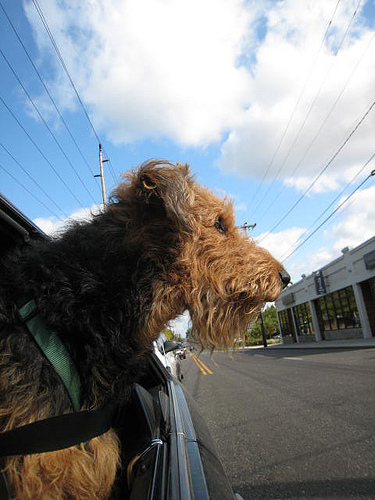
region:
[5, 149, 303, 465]
dog looking out of car window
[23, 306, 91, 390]
green collar on neck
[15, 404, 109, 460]
black safety belt across chest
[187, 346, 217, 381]
yellow lines in road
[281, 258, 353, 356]
store front with windows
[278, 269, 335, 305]
signs on storefront over windows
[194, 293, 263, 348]
wiry fur on chin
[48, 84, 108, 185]
power lines and wood pole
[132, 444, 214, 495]
lock button on car door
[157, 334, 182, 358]
side view mirror on car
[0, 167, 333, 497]
Dog holding its head outside a car window.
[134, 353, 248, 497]
Black car with windows down.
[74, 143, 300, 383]
Brown terrier dog.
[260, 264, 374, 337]
Storefronts with large glass windows.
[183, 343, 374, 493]
Paved street with yellow lane divider.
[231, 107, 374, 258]
Multiple telephone and power lines.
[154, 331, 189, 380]
White car with black rear view mirror.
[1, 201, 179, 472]
Dog with canvas restraints.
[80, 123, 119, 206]
Wooden pole with electric wires.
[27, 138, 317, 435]
Brown dog with black fur on its neck.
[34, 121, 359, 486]
a dog looking from a vehicle window.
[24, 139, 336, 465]
nice dog looking from a vehicle window.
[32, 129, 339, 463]
adorable dog looking from a vehicle window.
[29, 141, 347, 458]
a cute dog looking from a vehicle window.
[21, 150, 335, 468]
curious dog looking from a vehicle window.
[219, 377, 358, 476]
cement roadway area in view.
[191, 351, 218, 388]
yellow lines in roadway.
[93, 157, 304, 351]
head of a dog.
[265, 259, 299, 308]
nose of a dog.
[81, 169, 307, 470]
brown dog staring from a vehicle.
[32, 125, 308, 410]
nice dog with head outside window.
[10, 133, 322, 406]
hairy dog with head outside window.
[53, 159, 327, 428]
interested dog with head outside window.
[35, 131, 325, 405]
very curious dog with head outside window.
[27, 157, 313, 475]
nosy dog with head outside window.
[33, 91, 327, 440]
friendly dog with head outside window.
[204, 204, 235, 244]
right eye of a brown dog.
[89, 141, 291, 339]
head of a curious brown dog.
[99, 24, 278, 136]
beautiful blue sky with clouds.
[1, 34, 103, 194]
power lines in public view.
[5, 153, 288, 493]
the dog is facing right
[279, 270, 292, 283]
the dog has a black nose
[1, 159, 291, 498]
the dog is light brown in color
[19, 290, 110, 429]
the dog is wearing a collar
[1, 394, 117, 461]
the seat belt is across the dog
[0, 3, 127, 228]
power lines are high up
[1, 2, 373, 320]
the sky is blue in color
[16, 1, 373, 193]
the sky is full of clouds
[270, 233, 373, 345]
the building is white in color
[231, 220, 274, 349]
a pole is in the background